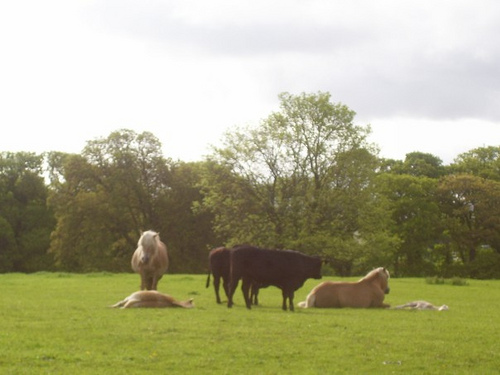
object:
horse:
[111, 291, 194, 310]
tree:
[190, 92, 371, 257]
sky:
[373, 26, 497, 141]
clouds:
[0, 1, 184, 120]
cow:
[205, 241, 269, 305]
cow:
[226, 245, 325, 311]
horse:
[131, 229, 169, 290]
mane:
[358, 267, 383, 284]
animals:
[297, 265, 390, 308]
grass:
[75, 315, 331, 359]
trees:
[0, 89, 190, 276]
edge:
[0, 271, 499, 282]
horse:
[395, 301, 449, 312]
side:
[395, 307, 449, 311]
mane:
[142, 229, 165, 241]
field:
[1, 277, 500, 375]